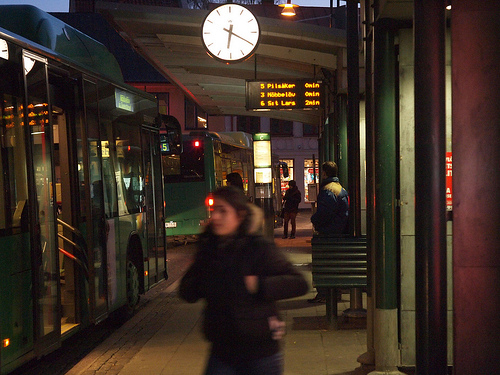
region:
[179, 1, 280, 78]
The clock is lite up.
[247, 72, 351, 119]
The writing is yellow.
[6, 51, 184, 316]
The bus is moving.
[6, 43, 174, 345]
There are people on the bus.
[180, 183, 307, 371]
The woman is walking.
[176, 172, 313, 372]
The woman is wearing a jacket.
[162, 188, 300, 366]
The woman is walking on the sidewalk.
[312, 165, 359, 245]
The man is standing.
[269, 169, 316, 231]
The woman is shopping.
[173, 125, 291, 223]
The bus is moving.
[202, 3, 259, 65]
a white clock displaying 6:20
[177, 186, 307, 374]
a girl walking down the sidewalk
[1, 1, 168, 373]
a city bus parked at the curb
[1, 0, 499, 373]
a night time picture of a bus terminal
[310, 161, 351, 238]
a man in a blue and yellow ski jacket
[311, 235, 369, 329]
a bus bench at the bus terminal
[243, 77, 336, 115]
a digital display of the arrival and departure times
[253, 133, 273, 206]
an information dispaly of the bus routes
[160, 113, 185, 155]
the buses rear view mirror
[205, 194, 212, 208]
the buses brake lights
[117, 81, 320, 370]
Trying to catch the bus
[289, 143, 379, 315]
Waiting in the background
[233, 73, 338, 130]
Bus schedule and arrival times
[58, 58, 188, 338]
Green bus parked next to curb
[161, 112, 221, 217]
Lights on back of bus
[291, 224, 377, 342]
Bench for waiting passengers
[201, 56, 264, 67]
A small portion of a clock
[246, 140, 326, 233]
Lights on in the stores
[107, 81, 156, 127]
Destination lit up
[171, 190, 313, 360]
Warm jacket hands in pocket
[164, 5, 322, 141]
a clock is hanging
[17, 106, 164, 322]
the door is open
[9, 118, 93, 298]
the door is open